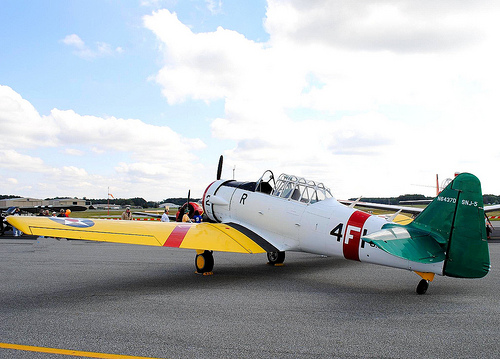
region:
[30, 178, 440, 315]
plane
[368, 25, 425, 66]
white clouds in blue sky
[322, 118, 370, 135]
white clouds in blue sky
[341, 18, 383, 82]
white clouds in blue sky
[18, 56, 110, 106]
white clouds in blue sky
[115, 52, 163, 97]
white clouds in blue sky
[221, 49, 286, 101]
white clouds in blue sky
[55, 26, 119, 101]
white clouds in blue sky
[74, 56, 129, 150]
white clouds in blue sky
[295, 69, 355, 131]
white clouds in blue sky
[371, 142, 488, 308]
the tail of the plane is green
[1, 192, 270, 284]
the wings are yellow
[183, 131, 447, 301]
the body of the plane is white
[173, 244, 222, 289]
the wheel is black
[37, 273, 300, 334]
the ground is grey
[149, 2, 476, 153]
the sky is mostly cloudy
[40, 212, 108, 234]
a circle on the wing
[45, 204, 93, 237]
the circle is blue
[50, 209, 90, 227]
a star is inside the circle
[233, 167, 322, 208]
the plane is empty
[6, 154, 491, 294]
Plane on the ground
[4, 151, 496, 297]
Plane is on the ground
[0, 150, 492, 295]
Airplane on the ground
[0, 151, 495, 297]
Airplane is on the ground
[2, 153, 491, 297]
Plane on a runway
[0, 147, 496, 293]
Plane is on a runway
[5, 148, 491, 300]
Airplane on a runway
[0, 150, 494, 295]
Airplane is on a runway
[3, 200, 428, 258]
Plane's wings are yellow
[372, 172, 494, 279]
Plane's tail is green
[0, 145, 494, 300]
small multi colored aeroplane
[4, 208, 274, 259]
yellow plane wing with a diagonal red stripe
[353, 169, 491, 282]
green tail of a plane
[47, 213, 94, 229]
red circle inside a white star inside a blue circle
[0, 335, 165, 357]
yellow line painted on tarmac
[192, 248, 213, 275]
black rubber plane tire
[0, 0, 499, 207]
light blue cloudy sky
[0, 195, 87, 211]
small group of tan buildings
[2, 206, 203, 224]
group of several people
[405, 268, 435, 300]
plane's back tire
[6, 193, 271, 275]
wings of a airplane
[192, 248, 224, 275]
wheels of a plane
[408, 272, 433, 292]
wheels of a plane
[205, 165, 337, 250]
cockpit of a plane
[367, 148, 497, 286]
back wings of a plane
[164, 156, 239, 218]
front motor of a plane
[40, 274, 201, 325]
shadows of a plane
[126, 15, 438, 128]
sky full of clouds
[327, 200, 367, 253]
numbers and letter on plane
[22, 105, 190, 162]
a cloudy sky